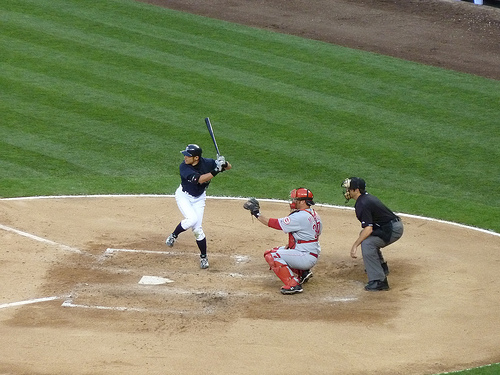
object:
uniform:
[171, 156, 230, 258]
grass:
[0, 0, 500, 233]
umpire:
[340, 175, 402, 293]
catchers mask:
[286, 185, 298, 214]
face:
[182, 156, 194, 165]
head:
[179, 142, 202, 167]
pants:
[173, 184, 206, 242]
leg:
[173, 188, 198, 239]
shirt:
[176, 157, 225, 197]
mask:
[338, 178, 350, 202]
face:
[346, 189, 360, 199]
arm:
[180, 167, 217, 184]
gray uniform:
[277, 207, 322, 267]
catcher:
[242, 187, 322, 295]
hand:
[214, 157, 224, 172]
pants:
[359, 217, 402, 284]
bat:
[203, 116, 221, 155]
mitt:
[241, 197, 259, 225]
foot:
[164, 233, 176, 248]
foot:
[280, 285, 303, 295]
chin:
[183, 160, 191, 165]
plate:
[136, 271, 173, 284]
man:
[164, 142, 231, 269]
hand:
[243, 198, 263, 218]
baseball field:
[0, 0, 500, 374]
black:
[375, 201, 386, 217]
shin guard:
[262, 249, 295, 290]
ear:
[192, 156, 199, 161]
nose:
[182, 155, 189, 159]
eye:
[187, 155, 193, 159]